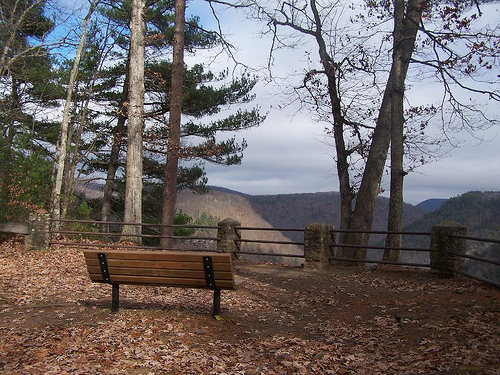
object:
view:
[99, 112, 498, 282]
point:
[86, 222, 255, 316]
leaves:
[115, 313, 276, 370]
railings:
[242, 226, 305, 232]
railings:
[249, 239, 301, 245]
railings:
[240, 252, 303, 257]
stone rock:
[429, 216, 469, 276]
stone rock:
[302, 220, 339, 272]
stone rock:
[215, 219, 239, 265]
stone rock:
[26, 211, 50, 253]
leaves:
[276, 278, 406, 365]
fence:
[70, 200, 398, 264]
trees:
[268, 0, 355, 263]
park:
[1, 2, 496, 371]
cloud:
[262, 129, 333, 187]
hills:
[124, 193, 300, 262]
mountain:
[360, 187, 497, 284]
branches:
[169, 61, 261, 184]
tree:
[125, 1, 151, 247]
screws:
[102, 261, 105, 264]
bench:
[83, 251, 236, 314]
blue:
[251, 127, 319, 175]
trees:
[387, 0, 407, 268]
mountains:
[406, 197, 455, 219]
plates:
[96, 248, 223, 285]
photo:
[6, 8, 484, 357]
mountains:
[251, 188, 420, 241]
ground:
[0, 256, 437, 366]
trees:
[49, 11, 88, 216]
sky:
[275, 121, 311, 183]